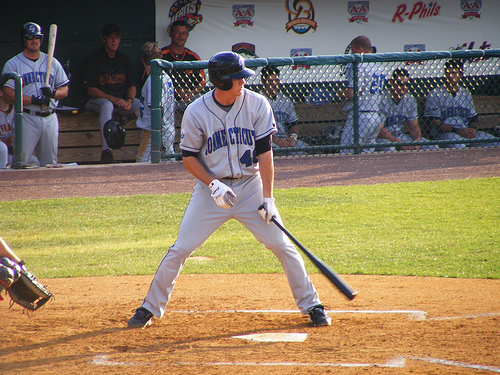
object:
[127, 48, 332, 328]
man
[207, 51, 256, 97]
head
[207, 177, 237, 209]
hand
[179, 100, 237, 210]
arm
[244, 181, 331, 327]
leg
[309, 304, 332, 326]
foot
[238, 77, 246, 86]
nose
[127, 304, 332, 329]
shoes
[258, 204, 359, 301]
bat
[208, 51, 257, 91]
hat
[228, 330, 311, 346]
home plate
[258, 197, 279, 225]
left hand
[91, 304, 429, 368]
chalk box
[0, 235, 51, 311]
catcher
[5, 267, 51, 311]
glove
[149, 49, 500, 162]
chain link fence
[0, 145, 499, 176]
edge of field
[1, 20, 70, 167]
man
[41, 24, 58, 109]
bat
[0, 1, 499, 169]
background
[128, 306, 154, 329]
left foot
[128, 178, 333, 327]
wide legs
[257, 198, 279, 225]
glove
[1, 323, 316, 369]
shadow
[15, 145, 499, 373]
field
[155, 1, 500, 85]
board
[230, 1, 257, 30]
product logo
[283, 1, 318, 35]
product logo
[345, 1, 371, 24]
product logo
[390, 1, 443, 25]
product logo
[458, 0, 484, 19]
product logo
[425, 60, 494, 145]
player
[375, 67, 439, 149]
player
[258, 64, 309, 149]
player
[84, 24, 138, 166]
player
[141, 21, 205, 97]
player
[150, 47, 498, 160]
railing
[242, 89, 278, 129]
left shoulder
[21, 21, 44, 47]
helmet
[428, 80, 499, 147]
uniform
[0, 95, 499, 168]
bench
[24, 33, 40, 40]
sunglasses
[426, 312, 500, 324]
line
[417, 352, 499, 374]
line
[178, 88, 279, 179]
shirt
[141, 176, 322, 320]
pants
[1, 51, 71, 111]
shirt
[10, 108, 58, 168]
pants